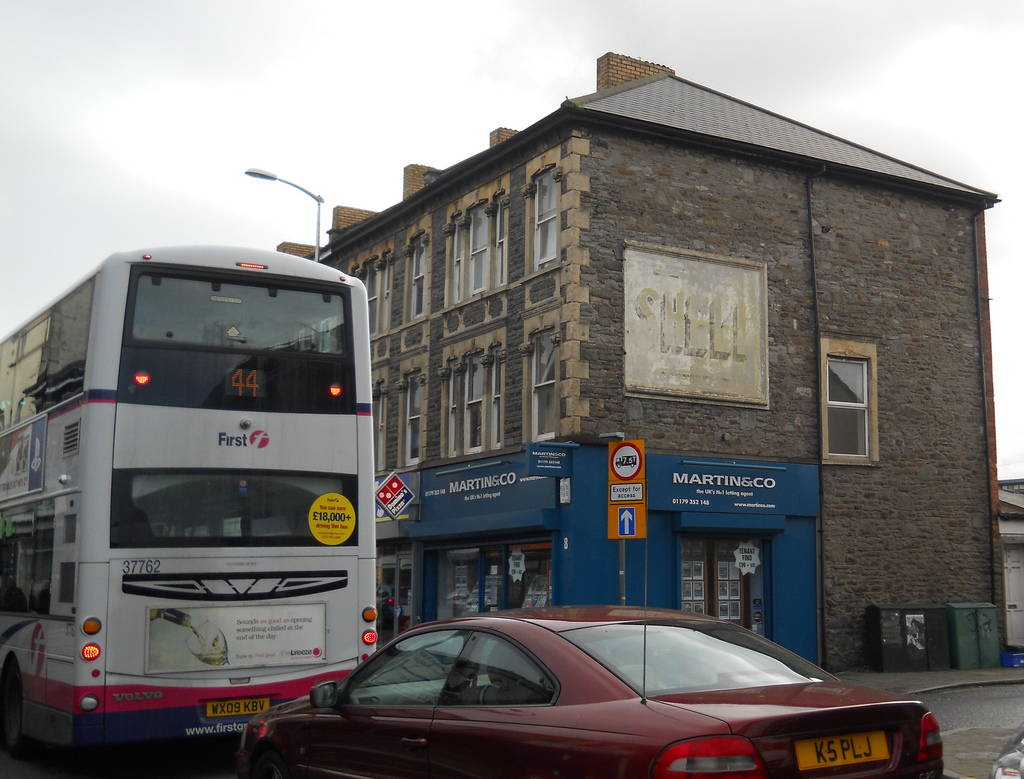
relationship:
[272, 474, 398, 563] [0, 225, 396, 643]
circle on bus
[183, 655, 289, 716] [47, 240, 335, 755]
plate on bus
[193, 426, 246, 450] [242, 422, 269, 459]
company's name and logo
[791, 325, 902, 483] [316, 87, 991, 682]
window on side of building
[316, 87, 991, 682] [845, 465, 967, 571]
building made of brick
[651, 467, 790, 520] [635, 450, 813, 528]
writing on background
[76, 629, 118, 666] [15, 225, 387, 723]
light on bus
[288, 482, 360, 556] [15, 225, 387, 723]
sign on bus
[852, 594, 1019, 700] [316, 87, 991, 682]
trash cans on side of building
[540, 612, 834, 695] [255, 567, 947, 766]
window on back of car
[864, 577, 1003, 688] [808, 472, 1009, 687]
structures against wall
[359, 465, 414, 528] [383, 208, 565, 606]
restaurant sign on wall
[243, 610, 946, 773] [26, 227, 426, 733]
car behind bus